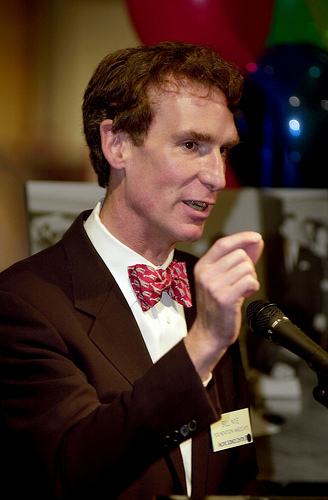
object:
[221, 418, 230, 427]
word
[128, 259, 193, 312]
design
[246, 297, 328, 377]
microphone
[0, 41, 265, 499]
man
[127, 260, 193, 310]
tie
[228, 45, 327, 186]
balloon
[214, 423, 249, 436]
word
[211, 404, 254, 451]
tag